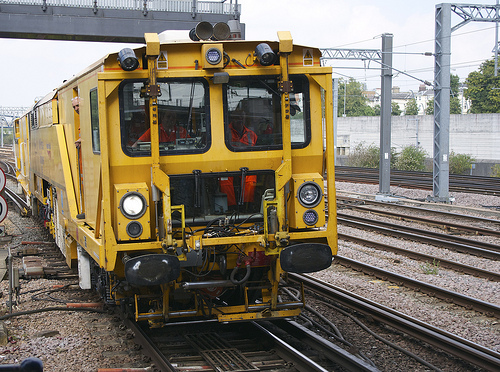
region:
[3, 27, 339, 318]
A yellow train on tracks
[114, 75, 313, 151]
Windows on a train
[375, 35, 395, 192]
A tall gray post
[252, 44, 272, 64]
A spotlight on a train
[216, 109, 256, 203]
A man inside a train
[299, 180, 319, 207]
A headlight on a train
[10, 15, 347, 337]
yellow train on train tracks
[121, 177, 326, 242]
white headlights on front of train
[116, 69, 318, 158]
windshield on front of train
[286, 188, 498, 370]
brown metal train tracks on ground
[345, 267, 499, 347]
gavel on side of train tracks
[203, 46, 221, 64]
light near roof on front of train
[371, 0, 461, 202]
metal poles on side of train tracks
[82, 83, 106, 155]
window on side of yellow train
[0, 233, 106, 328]
wires on ground next to train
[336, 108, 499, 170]
white wall on side of train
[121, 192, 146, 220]
headlight on a yellow train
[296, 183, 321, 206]
headlight on a yellow train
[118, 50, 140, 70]
headlight on a yellow train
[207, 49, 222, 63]
headlight on a yellow train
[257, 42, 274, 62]
headlight on a yellow train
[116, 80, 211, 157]
window on a yellow train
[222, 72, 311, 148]
window on a yellow train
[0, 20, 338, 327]
yellow train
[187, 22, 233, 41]
horn on a yellow train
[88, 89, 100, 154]
window on a yellow train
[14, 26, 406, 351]
Large train engine is on the tracks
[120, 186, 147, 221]
Train has one light turned on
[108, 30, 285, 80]
Train has spot lights turned off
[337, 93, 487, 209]
Wall is made of bricks on the far right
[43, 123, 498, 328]
Several tracks are seen in the train yard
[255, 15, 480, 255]
Large poles are built in the yard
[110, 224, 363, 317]
Train has large bumpers on each side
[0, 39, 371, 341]
Train engine has one car attached to it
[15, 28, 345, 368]
Train has 2 windows on the front of it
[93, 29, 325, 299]
Train has 7 total lights on the front of it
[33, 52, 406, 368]
a yellow train on track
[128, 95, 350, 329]
a yellow short train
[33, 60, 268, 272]
a short yellow trian on track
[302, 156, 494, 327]
train tracks next to each other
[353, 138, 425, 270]
gravel in train tracks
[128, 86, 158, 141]
window on train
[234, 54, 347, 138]
window on train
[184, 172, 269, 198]
window on trani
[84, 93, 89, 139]
window n train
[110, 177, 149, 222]
light on train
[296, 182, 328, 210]
the light is out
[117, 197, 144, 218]
the light is on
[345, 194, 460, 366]
several sets of tracks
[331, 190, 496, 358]
the tracks are steel